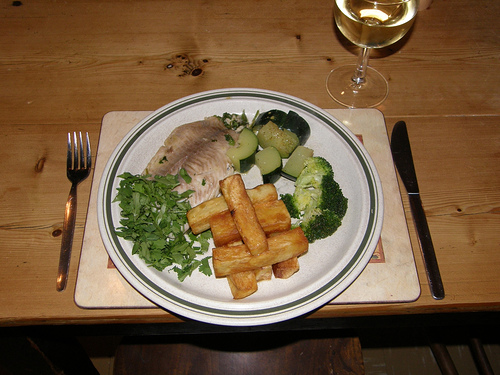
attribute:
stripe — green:
[102, 90, 378, 317]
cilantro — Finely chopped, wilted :
[118, 169, 213, 279]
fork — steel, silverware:
[52, 129, 98, 295]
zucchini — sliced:
[284, 142, 313, 179]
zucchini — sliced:
[254, 145, 284, 180]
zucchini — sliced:
[229, 124, 261, 170]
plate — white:
[74, 73, 413, 338]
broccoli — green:
[303, 179, 345, 216]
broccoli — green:
[300, 209, 342, 244]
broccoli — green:
[293, 157, 334, 189]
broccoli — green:
[278, 192, 314, 219]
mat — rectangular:
[83, 102, 415, 284]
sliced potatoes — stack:
[181, 181, 303, 287]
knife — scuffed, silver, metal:
[391, 121, 447, 306]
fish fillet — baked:
[139, 112, 236, 194]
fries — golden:
[193, 174, 311, 289]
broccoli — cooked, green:
[282, 118, 379, 267]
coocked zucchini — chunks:
[228, 120, 314, 182]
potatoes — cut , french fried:
[186, 173, 308, 296]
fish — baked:
[143, 115, 237, 208]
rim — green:
[100, 90, 377, 318]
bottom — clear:
[329, 62, 389, 108]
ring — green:
[102, 89, 382, 320]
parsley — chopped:
[113, 169, 213, 280]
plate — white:
[91, 78, 394, 333]